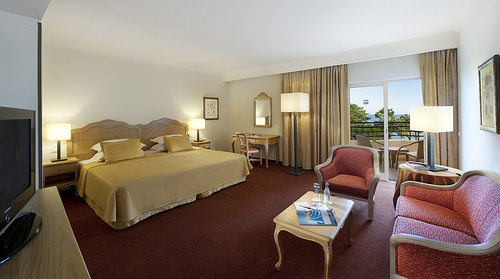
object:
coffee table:
[272, 188, 355, 278]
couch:
[387, 169, 499, 278]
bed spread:
[76, 145, 253, 223]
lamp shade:
[281, 92, 310, 112]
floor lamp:
[280, 90, 310, 177]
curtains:
[278, 63, 348, 171]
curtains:
[416, 47, 458, 169]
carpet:
[59, 154, 397, 278]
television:
[1, 105, 44, 263]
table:
[1, 183, 92, 278]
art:
[476, 52, 499, 136]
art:
[202, 96, 220, 120]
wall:
[456, 8, 499, 180]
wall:
[42, 37, 228, 166]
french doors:
[346, 77, 426, 185]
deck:
[350, 140, 426, 184]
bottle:
[322, 181, 332, 204]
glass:
[309, 182, 321, 204]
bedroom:
[0, 0, 499, 278]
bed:
[65, 117, 253, 229]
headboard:
[68, 115, 190, 162]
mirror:
[254, 99, 270, 128]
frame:
[253, 91, 273, 128]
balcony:
[345, 121, 425, 183]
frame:
[476, 51, 499, 136]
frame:
[202, 96, 221, 121]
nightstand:
[43, 155, 79, 195]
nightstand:
[191, 141, 211, 150]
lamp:
[44, 123, 72, 164]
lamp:
[191, 117, 206, 143]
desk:
[229, 130, 280, 169]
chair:
[395, 139, 425, 169]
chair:
[355, 131, 384, 167]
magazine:
[291, 200, 338, 229]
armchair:
[314, 142, 380, 223]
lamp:
[408, 106, 455, 171]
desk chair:
[234, 132, 263, 170]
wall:
[226, 72, 283, 164]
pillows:
[99, 138, 145, 162]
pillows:
[163, 134, 196, 154]